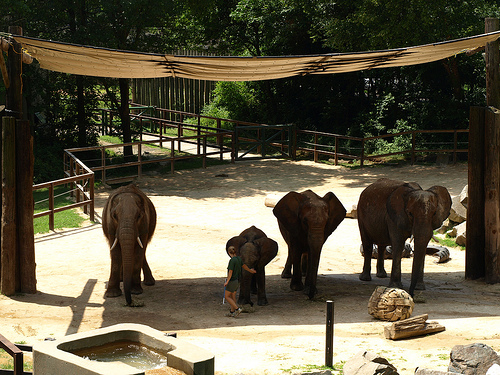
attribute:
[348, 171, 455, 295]
elephant — largest, in the scene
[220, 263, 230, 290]
arm — on person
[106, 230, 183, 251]
tusks — pointy, white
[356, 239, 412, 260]
tire — old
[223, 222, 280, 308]
elephant — young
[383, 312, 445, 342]
wood — piece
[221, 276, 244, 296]
shorts — gray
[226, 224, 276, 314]
elephant — baby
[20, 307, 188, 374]
container — square, cement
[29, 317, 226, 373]
trough — drinking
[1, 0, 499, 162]
trees — green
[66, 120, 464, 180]
fence — wooden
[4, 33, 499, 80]
canopy — tan 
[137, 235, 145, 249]
tusk — white 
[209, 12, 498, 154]
trees — leafy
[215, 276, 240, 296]
shirt — Green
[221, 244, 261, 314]
woman — in green